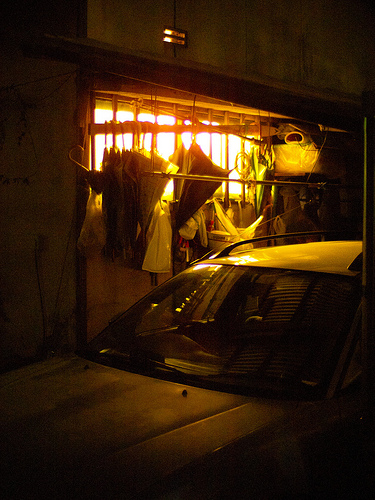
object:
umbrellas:
[173, 141, 231, 233]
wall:
[0, 0, 375, 373]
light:
[88, 90, 296, 270]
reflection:
[98, 264, 361, 389]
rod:
[87, 114, 282, 135]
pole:
[87, 119, 319, 136]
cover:
[215, 243, 322, 281]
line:
[252, 273, 317, 381]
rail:
[102, 146, 366, 259]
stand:
[88, 125, 172, 215]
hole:
[84, 363, 90, 370]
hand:
[125, 118, 142, 138]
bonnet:
[0, 347, 313, 499]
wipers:
[173, 370, 179, 374]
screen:
[76, 263, 359, 400]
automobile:
[0, 223, 375, 500]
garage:
[0, 0, 375, 499]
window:
[79, 67, 363, 270]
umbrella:
[87, 141, 231, 258]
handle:
[192, 88, 203, 117]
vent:
[0, 0, 86, 59]